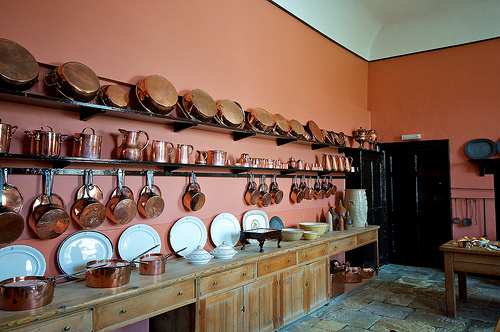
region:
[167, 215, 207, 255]
A round white plate.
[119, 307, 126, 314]
The handle of a drawer.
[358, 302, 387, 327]
Part of the floor.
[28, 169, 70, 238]
Pans hanging from the wall.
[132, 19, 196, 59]
Part of the wall.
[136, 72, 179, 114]
A copper pan.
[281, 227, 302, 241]
A yellow and white bowl.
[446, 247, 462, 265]
Part of the table.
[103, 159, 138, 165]
Part of a shelf.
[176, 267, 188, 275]
Part of the counter.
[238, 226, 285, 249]
small brown tray with legs on the counter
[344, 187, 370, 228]
tall white glass jug on the end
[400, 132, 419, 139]
white fixture above the door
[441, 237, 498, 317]
short brown wood table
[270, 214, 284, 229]
small blue plate on the shelf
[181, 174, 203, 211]
copper pot on the wall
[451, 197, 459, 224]
soup ladel next to the door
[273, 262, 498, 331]
rock and stone flooring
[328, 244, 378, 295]
open section of the counter with pots in it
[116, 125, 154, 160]
largest copper pitcher with a handle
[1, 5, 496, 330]
roo with orange walls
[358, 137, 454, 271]
open door of room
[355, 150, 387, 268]
surface of black door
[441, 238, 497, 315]
corner of wood table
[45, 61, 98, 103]
bottom of copper pan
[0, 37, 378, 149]
copper pots on shelf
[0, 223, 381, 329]
long wood furniture against wall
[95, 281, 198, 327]
drawer with two knobs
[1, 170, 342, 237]
pans hanging from hooks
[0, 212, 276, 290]
plates standing against wall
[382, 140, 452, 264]
the door is black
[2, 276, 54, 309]
the pot is brass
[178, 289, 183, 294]
metal drawer pull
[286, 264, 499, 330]
stone flooring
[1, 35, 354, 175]
two shelves of dishes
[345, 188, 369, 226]
a large white vase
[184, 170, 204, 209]
the pot is hanging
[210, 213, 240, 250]
a white serving platter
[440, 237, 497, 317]
small wooden table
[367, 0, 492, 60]
arched ceiling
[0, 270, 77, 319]
copper pot on table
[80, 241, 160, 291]
copper pot on shelf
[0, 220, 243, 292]
serving platters on wall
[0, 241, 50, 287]
white serving platter on table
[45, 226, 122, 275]
white serving platter on table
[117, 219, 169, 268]
white serving platter on table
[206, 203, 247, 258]
white serving platter on table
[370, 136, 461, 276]
door in orange wall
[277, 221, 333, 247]
brown bowls on shelf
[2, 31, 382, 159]
pots on wall